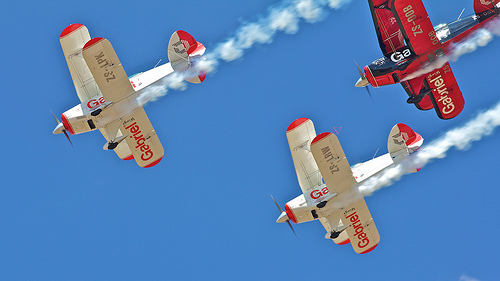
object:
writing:
[84, 98, 100, 109]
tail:
[165, 30, 211, 84]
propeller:
[44, 108, 75, 149]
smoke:
[398, 17, 500, 84]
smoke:
[328, 103, 499, 210]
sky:
[0, 0, 499, 280]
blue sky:
[0, 0, 499, 280]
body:
[48, 24, 208, 169]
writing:
[139, 149, 155, 162]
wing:
[117, 105, 165, 169]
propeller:
[267, 193, 300, 240]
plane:
[353, 1, 499, 121]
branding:
[268, 118, 426, 254]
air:
[0, 0, 498, 280]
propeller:
[350, 60, 375, 101]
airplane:
[49, 23, 208, 169]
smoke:
[93, 0, 355, 129]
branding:
[48, 23, 209, 168]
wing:
[421, 62, 465, 121]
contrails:
[91, 0, 353, 128]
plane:
[270, 84, 450, 267]